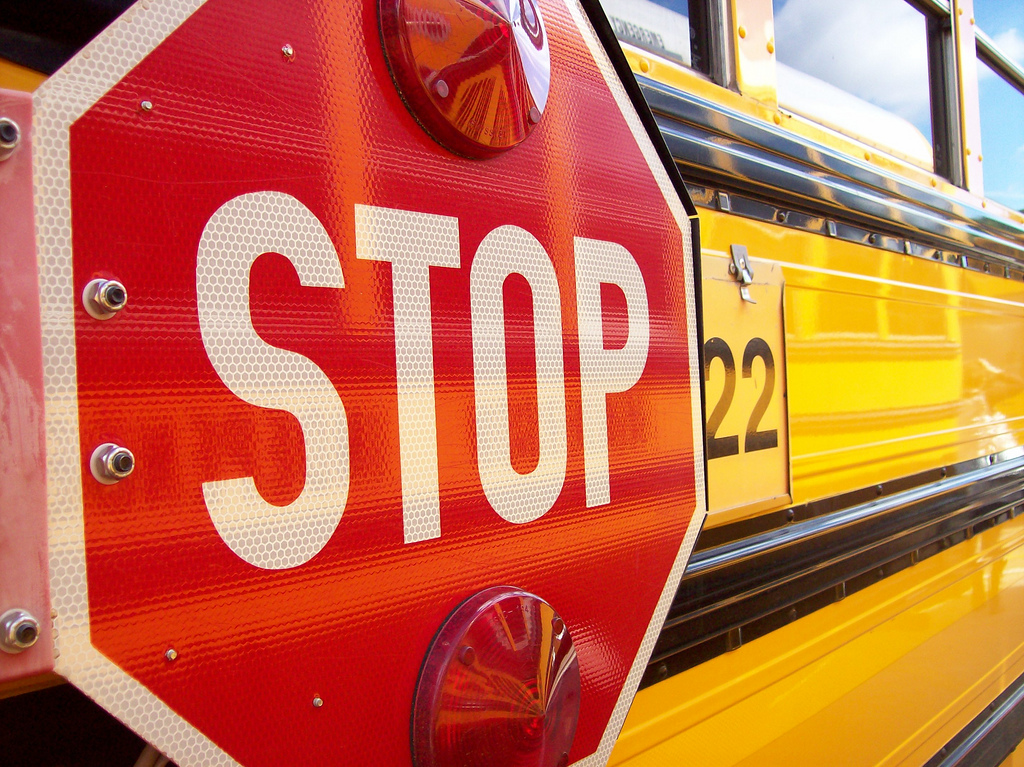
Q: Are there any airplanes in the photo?
A: No, there are no airplanes.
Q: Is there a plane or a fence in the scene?
A: No, there are no airplanes or fences.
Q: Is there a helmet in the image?
A: No, there are no helmets.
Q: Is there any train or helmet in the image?
A: No, there are no helmets or trains.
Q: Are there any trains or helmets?
A: No, there are no helmets or trains.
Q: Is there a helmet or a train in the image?
A: No, there are no helmets or trains.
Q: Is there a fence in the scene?
A: No, there are no fences.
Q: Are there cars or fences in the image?
A: No, there are no fences or cars.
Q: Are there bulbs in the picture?
A: No, there are no bulbs.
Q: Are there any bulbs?
A: No, there are no bulbs.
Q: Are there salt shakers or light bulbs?
A: No, there are no light bulbs or salt shakers.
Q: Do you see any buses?
A: Yes, there is a bus.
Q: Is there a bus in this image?
A: Yes, there is a bus.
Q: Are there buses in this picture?
A: Yes, there is a bus.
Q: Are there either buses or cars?
A: Yes, there is a bus.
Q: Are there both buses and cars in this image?
A: No, there is a bus but no cars.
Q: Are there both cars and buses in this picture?
A: No, there is a bus but no cars.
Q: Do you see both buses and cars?
A: No, there is a bus but no cars.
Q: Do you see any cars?
A: No, there are no cars.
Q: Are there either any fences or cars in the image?
A: No, there are no cars or fences.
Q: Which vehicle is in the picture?
A: The vehicle is a bus.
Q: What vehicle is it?
A: The vehicle is a bus.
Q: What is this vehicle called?
A: This is a bus.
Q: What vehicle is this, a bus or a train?
A: This is a bus.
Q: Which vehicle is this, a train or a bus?
A: This is a bus.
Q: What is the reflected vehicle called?
A: The vehicle is a bus.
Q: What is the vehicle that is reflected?
A: The vehicle is a bus.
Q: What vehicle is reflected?
A: The vehicle is a bus.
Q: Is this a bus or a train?
A: This is a bus.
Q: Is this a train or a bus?
A: This is a bus.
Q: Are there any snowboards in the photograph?
A: No, there are no snowboards.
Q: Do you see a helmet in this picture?
A: No, there are no helmets.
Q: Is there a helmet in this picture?
A: No, there are no helmets.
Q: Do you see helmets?
A: No, there are no helmets.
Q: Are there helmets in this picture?
A: No, there are no helmets.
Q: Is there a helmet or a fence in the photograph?
A: No, there are no helmets or fences.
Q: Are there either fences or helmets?
A: No, there are no helmets or fences.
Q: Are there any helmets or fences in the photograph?
A: No, there are no helmets or fences.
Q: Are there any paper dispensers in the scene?
A: No, there are no paper dispensers.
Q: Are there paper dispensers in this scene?
A: No, there are no paper dispensers.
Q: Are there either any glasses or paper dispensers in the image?
A: No, there are no paper dispensers or glasses.